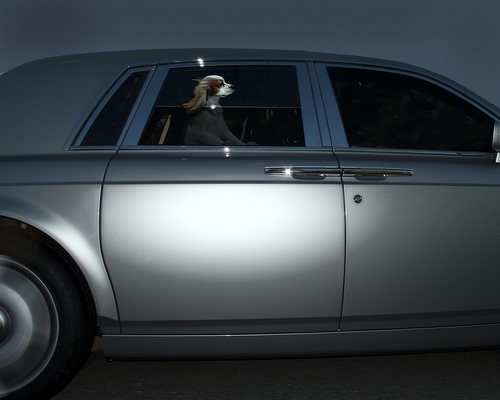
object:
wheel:
[0, 217, 97, 395]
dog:
[177, 69, 248, 154]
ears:
[182, 83, 220, 115]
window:
[322, 62, 415, 152]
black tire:
[0, 222, 95, 398]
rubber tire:
[0, 217, 95, 398]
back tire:
[0, 217, 97, 398]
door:
[90, 51, 361, 348]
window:
[140, 106, 305, 146]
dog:
[178, 64, 267, 121]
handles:
[263, 163, 417, 187]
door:
[99, 61, 344, 336]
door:
[304, 52, 498, 322]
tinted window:
[323, 65, 496, 155]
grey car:
[3, 48, 496, 352]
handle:
[356, 171, 387, 181]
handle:
[284, 163, 393, 187]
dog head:
[193, 67, 240, 106]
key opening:
[352, 192, 362, 204]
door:
[313, 60, 499, 332]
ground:
[322, 101, 352, 136]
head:
[184, 72, 234, 108]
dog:
[183, 72, 254, 147]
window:
[138, 62, 305, 147]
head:
[193, 74, 235, 104]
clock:
[26, 212, 95, 397]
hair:
[181, 78, 208, 113]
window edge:
[163, 94, 295, 112]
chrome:
[0, 49, 493, 394]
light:
[51, 171, 390, 280]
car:
[3, 39, 490, 384]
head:
[199, 74, 234, 96]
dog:
[171, 66, 254, 158]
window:
[117, 61, 335, 170]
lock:
[352, 195, 361, 202]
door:
[101, 154, 345, 333]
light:
[92, 182, 384, 278]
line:
[299, 52, 335, 146]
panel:
[299, 63, 343, 146]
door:
[93, 50, 352, 330]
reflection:
[112, 173, 332, 311]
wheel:
[0, 230, 100, 385]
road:
[93, 356, 480, 392]